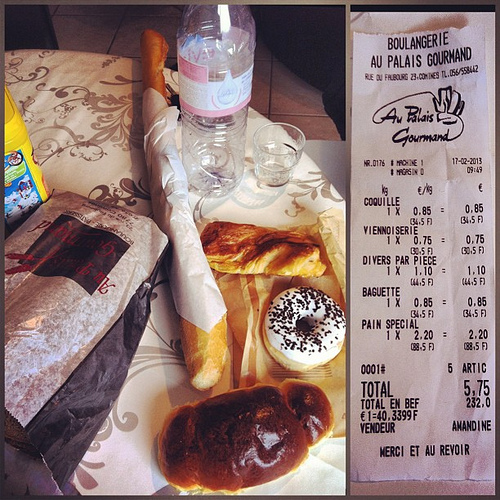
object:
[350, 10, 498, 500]
receipt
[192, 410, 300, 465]
top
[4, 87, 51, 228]
yellow container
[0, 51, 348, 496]
tablecloth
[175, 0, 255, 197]
bottle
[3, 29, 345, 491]
pastry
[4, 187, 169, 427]
bag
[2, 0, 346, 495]
table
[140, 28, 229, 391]
baguette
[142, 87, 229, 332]
paper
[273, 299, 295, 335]
sprinkles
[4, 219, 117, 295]
bad sentance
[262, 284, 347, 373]
donut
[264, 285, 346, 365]
white icing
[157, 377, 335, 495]
brioche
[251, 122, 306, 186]
glass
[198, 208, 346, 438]
bag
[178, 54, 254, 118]
label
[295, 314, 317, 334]
center